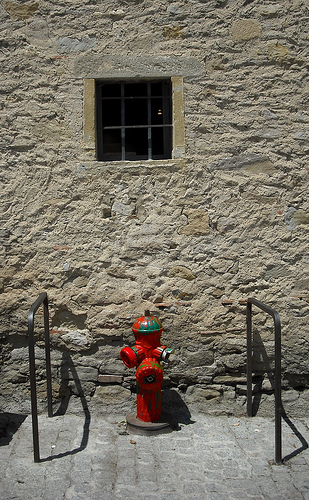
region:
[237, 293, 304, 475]
rail near a wall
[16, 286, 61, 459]
rail near a wall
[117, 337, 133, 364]
knob on a hydrant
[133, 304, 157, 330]
top of a hydrant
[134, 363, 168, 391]
knob on a hydrant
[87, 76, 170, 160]
window inset in wall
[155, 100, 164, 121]
light inside the building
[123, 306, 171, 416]
red fire hydrant with green paint flecks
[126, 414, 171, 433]
cement base of the fire hydrant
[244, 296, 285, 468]
black railing on the right side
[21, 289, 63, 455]
black railing on the left side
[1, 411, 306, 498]
gray stone walkway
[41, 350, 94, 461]
shadow of the railing on the left side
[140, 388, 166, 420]
shadow on the fire hydrant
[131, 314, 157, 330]
red and green top on the fire hydrant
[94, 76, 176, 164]
small window has bars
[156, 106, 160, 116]
light hanging indoor behind window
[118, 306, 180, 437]
fire hydrant in front of wall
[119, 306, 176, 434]
fire hydrant is red and green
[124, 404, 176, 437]
fire hydrant is on base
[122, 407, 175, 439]
base for hydrant is cement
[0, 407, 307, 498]
walkway in front of wall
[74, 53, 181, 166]
window in the stone wall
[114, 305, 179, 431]
red and green fire hydrant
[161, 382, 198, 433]
shadow of the fire hydrant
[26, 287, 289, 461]
black railings beside the fire hydrant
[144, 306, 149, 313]
bolt on top of the fire hydrant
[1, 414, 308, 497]
stone sidewalk fire hydrant is on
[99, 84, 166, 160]
bars on the window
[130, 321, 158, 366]
green paint on the fire hydrant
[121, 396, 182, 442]
bottom of the hydrant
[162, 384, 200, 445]
shadow of the hydrant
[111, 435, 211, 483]
lines on the ground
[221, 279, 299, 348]
pole next to the hydrant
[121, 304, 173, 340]
top of the hydrant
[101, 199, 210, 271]
rock wall above hydrant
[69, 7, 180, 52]
rock wall above the window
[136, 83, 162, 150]
bar on the window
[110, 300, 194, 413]
green and red hydrant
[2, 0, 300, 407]
stone wall composed of tan and gray rocks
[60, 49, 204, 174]
square window set into wall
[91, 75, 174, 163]
dark window with bars and tiny lights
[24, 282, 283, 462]
red and green fire hydrant set between black rails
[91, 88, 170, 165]
a window that is dark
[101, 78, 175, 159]
some bars that are on the window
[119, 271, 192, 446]
a hydrant that is red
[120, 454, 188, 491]
some bricks that are grey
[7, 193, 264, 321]
a wall that is made of rock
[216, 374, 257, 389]
A brick in a wall.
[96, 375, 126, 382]
A brick in a wall.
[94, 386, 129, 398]
A brick in a wall.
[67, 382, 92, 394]
A brick in a wall.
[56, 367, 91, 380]
A brick in a wall.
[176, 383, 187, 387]
A brick in a wall.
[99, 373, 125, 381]
A brick in a wall.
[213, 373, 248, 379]
A brick in a wall.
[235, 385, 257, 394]
A brick in a wall.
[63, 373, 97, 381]
A brick in a wall.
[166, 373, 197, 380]
A brick in a wall.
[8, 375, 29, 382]
A brick in a wall.